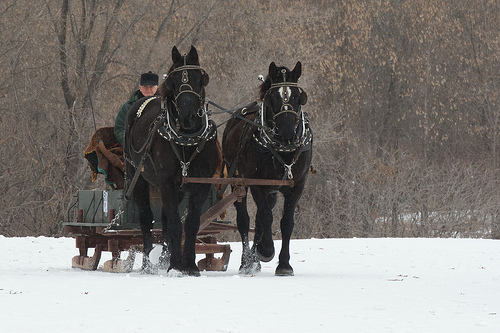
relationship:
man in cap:
[116, 70, 161, 140] [137, 71, 158, 88]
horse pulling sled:
[129, 39, 229, 275] [59, 180, 231, 270]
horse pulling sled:
[129, 39, 229, 275] [65, 214, 236, 274]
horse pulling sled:
[129, 39, 229, 275] [60, 201, 238, 273]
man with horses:
[116, 70, 161, 140] [122, 42, 323, 293]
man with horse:
[116, 70, 161, 140] [129, 39, 229, 275]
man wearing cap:
[116, 70, 161, 140] [134, 68, 157, 88]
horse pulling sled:
[129, 39, 229, 275] [60, 197, 234, 282]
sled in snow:
[60, 197, 234, 282] [88, 284, 359, 311]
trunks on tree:
[60, 176, 76, 226] [53, 5, 169, 140]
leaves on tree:
[350, 20, 370, 41] [336, 17, 456, 226]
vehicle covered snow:
[73, 246, 264, 279] [41, 295, 291, 330]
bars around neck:
[190, 166, 288, 233] [172, 130, 286, 152]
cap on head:
[136, 67, 158, 87] [133, 63, 159, 104]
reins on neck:
[141, 113, 320, 173] [165, 122, 215, 152]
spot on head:
[276, 82, 291, 104] [254, 62, 315, 172]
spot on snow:
[276, 82, 291, 104] [303, 246, 450, 306]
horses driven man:
[144, 44, 326, 291] [112, 65, 166, 145]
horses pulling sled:
[144, 44, 326, 291] [62, 208, 242, 277]